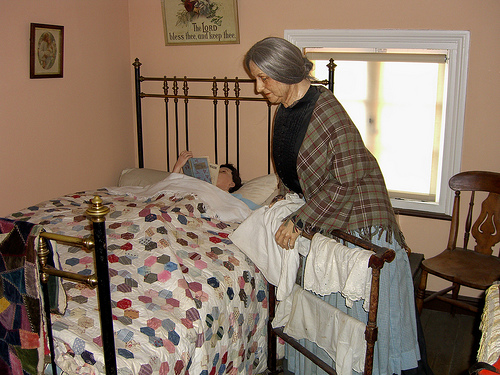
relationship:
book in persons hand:
[179, 156, 219, 185] [175, 146, 195, 168]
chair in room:
[412, 168, 498, 369] [3, 0, 498, 373]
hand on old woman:
[273, 220, 307, 250] [244, 34, 423, 374]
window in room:
[286, 24, 472, 218] [3, 0, 498, 373]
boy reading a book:
[166, 144, 244, 195] [168, 142, 219, 187]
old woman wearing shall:
[244, 34, 423, 374] [282, 82, 409, 244]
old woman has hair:
[244, 34, 423, 374] [265, 41, 298, 65]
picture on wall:
[29, 19, 65, 81] [0, 0, 137, 217]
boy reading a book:
[166, 144, 244, 195] [181, 157, 210, 181]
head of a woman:
[237, 44, 313, 101] [228, 46, 384, 287]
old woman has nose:
[244, 34, 423, 374] [254, 76, 264, 95]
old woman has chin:
[244, 34, 423, 374] [268, 96, 278, 103]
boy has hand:
[166, 144, 244, 195] [172, 147, 194, 167]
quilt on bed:
[0, 171, 272, 373] [0, 56, 336, 371]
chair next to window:
[412, 168, 498, 369] [286, 24, 472, 218]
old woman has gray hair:
[244, 34, 423, 374] [241, 34, 312, 87]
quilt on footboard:
[0, 217, 68, 373] [1, 194, 118, 374]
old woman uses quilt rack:
[244, 34, 423, 374] [270, 226, 385, 372]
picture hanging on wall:
[29, 19, 65, 81] [0, 0, 137, 217]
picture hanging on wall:
[154, 4, 244, 51] [128, 1, 484, 308]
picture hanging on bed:
[154, 4, 244, 51] [0, 56, 336, 371]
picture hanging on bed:
[29, 19, 65, 81] [0, 56, 336, 371]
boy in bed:
[166, 144, 244, 195] [0, 56, 336, 371]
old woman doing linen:
[244, 34, 423, 374] [226, 191, 308, 308]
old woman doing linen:
[244, 34, 423, 374] [299, 231, 379, 309]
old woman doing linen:
[244, 34, 423, 374] [268, 285, 373, 368]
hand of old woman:
[273, 220, 307, 250] [244, 34, 423, 374]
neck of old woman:
[234, 93, 360, 110] [244, 34, 423, 374]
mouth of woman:
[264, 89, 274, 98] [219, 15, 439, 364]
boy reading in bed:
[166, 144, 244, 195] [3, 42, 300, 372]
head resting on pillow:
[202, 145, 252, 202] [226, 172, 281, 205]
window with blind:
[286, 24, 472, 218] [304, 46, 448, 204]